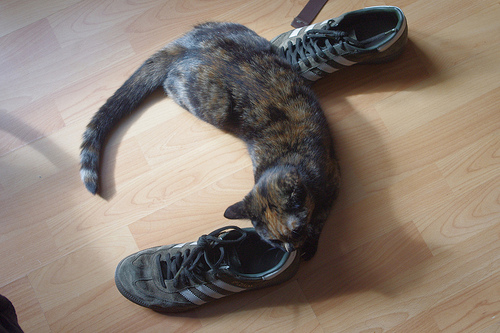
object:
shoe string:
[220, 225, 249, 242]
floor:
[347, 95, 483, 314]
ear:
[223, 200, 252, 221]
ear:
[282, 177, 312, 209]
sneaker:
[116, 222, 294, 314]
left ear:
[273, 175, 314, 204]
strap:
[283, 0, 360, 25]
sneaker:
[99, 222, 332, 325]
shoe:
[296, 23, 396, 64]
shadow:
[330, 102, 389, 293]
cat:
[80, 19, 347, 251]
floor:
[343, 97, 497, 332]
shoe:
[114, 236, 314, 307]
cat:
[71, 25, 357, 234]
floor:
[9, 30, 492, 330]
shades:
[121, 130, 203, 236]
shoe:
[270, 5, 407, 79]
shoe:
[113, 225, 303, 312]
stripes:
[179, 280, 248, 304]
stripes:
[298, 52, 355, 85]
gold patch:
[260, 205, 287, 239]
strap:
[285, 6, 322, 29]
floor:
[370, 69, 473, 176]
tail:
[79, 41, 182, 200]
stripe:
[83, 178, 100, 194]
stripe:
[77, 168, 104, 182]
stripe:
[78, 148, 101, 163]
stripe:
[78, 138, 108, 151]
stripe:
[80, 125, 107, 141]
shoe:
[94, 231, 323, 306]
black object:
[0, 293, 30, 331]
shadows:
[327, 99, 437, 301]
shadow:
[200, 90, 437, 320]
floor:
[1, 1, 497, 330]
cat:
[103, 46, 389, 249]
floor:
[2, 231, 497, 330]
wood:
[83, 212, 153, 329]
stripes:
[180, 273, 233, 328]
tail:
[74, 116, 134, 243]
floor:
[330, 67, 477, 331]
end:
[68, 157, 102, 195]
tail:
[77, 112, 119, 214]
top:
[115, 214, 296, 309]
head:
[227, 173, 314, 273]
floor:
[347, 109, 497, 209]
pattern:
[1, 244, 88, 315]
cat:
[68, 22, 358, 255]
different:
[14, 194, 88, 326]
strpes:
[174, 270, 232, 332]